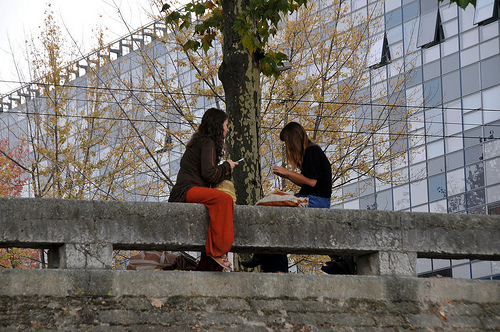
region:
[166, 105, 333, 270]
two women sitting on stone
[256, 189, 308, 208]
a white and brown bag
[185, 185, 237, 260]
one leg in orange pants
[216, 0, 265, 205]
a tree trunk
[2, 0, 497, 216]
blue windows on a building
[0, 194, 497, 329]
stone wall and bench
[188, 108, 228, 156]
curly dark brown hair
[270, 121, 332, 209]
woman in black shirt and blue bottoms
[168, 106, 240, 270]
woman in brown shirt and orange pants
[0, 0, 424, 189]
small orange leaves on trees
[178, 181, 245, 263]
the pants are orange in color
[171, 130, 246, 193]
the shirt is brown with orange on it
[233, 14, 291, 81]
the leaves are green and yellow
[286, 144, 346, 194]
the shirt is black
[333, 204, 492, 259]
the pillar is grey on color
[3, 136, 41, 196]
the leaves are red in color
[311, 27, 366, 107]
the leaves are gold in color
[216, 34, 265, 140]
the tree has moss on it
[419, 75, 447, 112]
the window is blueish grey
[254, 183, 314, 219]
the bag is orange and tan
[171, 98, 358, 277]
two women sitting on a ledge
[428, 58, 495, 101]
windows of a building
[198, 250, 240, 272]
right foot of a woman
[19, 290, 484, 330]
stone wall under ledge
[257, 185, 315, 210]
striped bag on a ledge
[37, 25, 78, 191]
tree behind the ledge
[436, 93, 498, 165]
electrical wires in the air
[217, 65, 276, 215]
trunk of a tree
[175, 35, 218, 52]
green leaves on a tree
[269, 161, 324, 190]
left arm of a woman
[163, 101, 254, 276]
girl with her cell phone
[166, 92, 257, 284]
girl with her mobile phone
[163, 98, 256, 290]
girl with her portable phone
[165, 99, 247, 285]
woman with her cell phone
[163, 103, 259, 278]
woman with her mobile phone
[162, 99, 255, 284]
woman with her portable phone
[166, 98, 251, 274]
girl texting on phone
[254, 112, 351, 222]
girl texting on phone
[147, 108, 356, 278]
two girls sitting dow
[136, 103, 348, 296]
two girls texting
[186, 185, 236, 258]
Pants are loose and red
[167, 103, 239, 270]
Woman holding cell phone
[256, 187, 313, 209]
Big bag next to woman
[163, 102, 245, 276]
Woman is sitting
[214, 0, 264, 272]
Tree trunk is large and green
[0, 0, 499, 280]
Building is large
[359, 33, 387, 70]
Glass window is open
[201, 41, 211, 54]
Leaf is green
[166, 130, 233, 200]
Jacket on woman is brown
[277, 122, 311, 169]
Hair covering face of woman